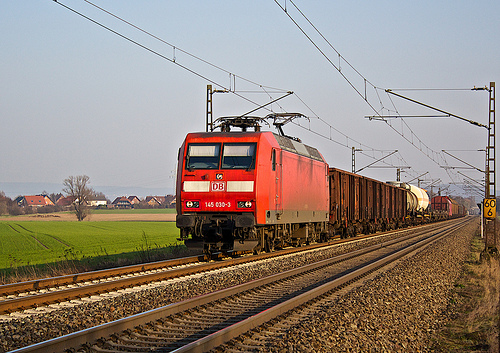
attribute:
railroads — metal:
[158, 250, 406, 350]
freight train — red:
[168, 107, 475, 252]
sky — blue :
[2, 1, 499, 204]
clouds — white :
[73, 145, 129, 157]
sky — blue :
[44, 80, 147, 118]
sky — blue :
[375, 22, 453, 62]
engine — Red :
[173, 128, 330, 248]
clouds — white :
[42, 17, 224, 99]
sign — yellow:
[483, 198, 496, 219]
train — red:
[174, 121, 462, 256]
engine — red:
[171, 117, 331, 262]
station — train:
[406, 75, 484, 317]